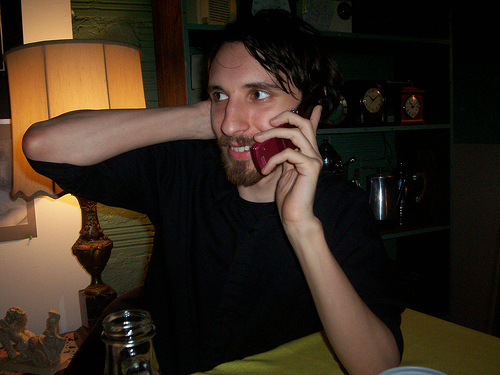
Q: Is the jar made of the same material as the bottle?
A: Yes, both the jar and the bottle are made of glass.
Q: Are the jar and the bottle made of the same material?
A: Yes, both the jar and the bottle are made of glass.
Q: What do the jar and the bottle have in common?
A: The material, both the jar and the bottle are glass.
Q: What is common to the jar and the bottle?
A: The material, both the jar and the bottle are glass.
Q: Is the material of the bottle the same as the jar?
A: Yes, both the bottle and the jar are made of glass.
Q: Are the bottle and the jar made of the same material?
A: Yes, both the bottle and the jar are made of glass.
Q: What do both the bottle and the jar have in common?
A: The material, both the bottle and the jar are glass.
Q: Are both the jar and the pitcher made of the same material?
A: No, the jar is made of glass and the pitcher is made of metal.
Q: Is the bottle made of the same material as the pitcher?
A: No, the bottle is made of glass and the pitcher is made of metal.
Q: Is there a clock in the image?
A: Yes, there is a clock.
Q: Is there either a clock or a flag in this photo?
A: Yes, there is a clock.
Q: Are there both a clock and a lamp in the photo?
A: Yes, there are both a clock and a lamp.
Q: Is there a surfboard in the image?
A: No, there are no surfboards.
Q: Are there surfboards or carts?
A: No, there are no surfboards or carts.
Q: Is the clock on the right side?
A: Yes, the clock is on the right of the image.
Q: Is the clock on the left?
A: No, the clock is on the right of the image.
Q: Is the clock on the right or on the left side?
A: The clock is on the right of the image.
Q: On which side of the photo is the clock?
A: The clock is on the right of the image.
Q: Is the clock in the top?
A: Yes, the clock is in the top of the image.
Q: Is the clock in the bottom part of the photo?
A: No, the clock is in the top of the image.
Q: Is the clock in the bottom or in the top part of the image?
A: The clock is in the top of the image.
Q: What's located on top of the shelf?
A: The clock is on top of the shelf.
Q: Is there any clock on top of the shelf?
A: Yes, there is a clock on top of the shelf.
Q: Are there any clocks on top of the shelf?
A: Yes, there is a clock on top of the shelf.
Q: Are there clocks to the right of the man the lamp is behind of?
A: Yes, there is a clock to the right of the man.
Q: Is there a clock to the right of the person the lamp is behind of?
A: Yes, there is a clock to the right of the man.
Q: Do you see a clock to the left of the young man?
A: No, the clock is to the right of the man.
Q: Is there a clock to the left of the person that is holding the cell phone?
A: No, the clock is to the right of the man.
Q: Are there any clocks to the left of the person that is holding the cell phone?
A: No, the clock is to the right of the man.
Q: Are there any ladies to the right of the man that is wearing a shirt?
A: No, there is a clock to the right of the man.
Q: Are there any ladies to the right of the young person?
A: No, there is a clock to the right of the man.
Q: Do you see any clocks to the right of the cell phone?
A: Yes, there is a clock to the right of the cell phone.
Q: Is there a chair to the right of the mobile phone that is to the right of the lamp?
A: No, there is a clock to the right of the cellphone.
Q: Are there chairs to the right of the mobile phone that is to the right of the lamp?
A: No, there is a clock to the right of the cellphone.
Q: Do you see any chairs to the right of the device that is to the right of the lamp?
A: No, there is a clock to the right of the cellphone.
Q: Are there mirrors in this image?
A: No, there are no mirrors.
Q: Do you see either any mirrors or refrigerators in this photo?
A: No, there are no mirrors or refrigerators.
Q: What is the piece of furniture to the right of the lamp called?
A: The piece of furniture is a shelf.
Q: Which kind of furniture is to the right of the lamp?
A: The piece of furniture is a shelf.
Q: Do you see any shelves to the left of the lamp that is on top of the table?
A: No, the shelf is to the right of the lamp.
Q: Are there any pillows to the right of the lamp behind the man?
A: No, there is a shelf to the right of the lamp.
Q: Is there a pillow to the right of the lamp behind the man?
A: No, there is a shelf to the right of the lamp.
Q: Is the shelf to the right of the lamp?
A: Yes, the shelf is to the right of the lamp.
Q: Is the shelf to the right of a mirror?
A: No, the shelf is to the right of the lamp.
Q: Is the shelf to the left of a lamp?
A: No, the shelf is to the right of a lamp.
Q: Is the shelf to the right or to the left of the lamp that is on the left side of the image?
A: The shelf is to the right of the lamp.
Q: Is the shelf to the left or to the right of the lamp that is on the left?
A: The shelf is to the right of the lamp.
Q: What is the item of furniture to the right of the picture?
A: The piece of furniture is a shelf.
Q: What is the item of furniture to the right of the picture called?
A: The piece of furniture is a shelf.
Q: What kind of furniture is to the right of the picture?
A: The piece of furniture is a shelf.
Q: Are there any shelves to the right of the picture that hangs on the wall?
A: Yes, there is a shelf to the right of the picture.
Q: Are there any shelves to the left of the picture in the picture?
A: No, the shelf is to the right of the picture.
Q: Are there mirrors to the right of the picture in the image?
A: No, there is a shelf to the right of the picture.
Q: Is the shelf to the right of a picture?
A: Yes, the shelf is to the right of a picture.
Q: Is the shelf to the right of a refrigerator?
A: No, the shelf is to the right of a picture.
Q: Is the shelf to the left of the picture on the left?
A: No, the shelf is to the right of the picture.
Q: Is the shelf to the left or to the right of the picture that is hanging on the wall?
A: The shelf is to the right of the picture.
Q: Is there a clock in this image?
A: Yes, there is a clock.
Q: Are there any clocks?
A: Yes, there is a clock.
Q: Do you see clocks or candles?
A: Yes, there is a clock.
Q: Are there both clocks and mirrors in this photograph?
A: No, there is a clock but no mirrors.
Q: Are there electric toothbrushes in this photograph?
A: No, there are no electric toothbrushes.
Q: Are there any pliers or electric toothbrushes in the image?
A: No, there are no electric toothbrushes or pliers.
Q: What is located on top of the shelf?
A: The clock is on top of the shelf.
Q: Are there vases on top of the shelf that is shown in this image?
A: No, there is a clock on top of the shelf.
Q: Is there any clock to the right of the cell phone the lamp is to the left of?
A: Yes, there is a clock to the right of the cell phone.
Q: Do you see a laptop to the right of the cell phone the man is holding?
A: No, there is a clock to the right of the mobile phone.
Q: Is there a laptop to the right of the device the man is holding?
A: No, there is a clock to the right of the mobile phone.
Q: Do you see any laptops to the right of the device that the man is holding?
A: No, there is a clock to the right of the mobile phone.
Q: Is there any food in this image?
A: No, there is no food.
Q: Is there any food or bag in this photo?
A: No, there are no food or bags.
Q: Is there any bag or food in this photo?
A: No, there are no food or bags.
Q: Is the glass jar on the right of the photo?
A: Yes, the jar is on the right of the image.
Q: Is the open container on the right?
A: Yes, the jar is on the right of the image.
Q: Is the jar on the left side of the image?
A: No, the jar is on the right of the image.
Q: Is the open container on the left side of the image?
A: No, the jar is on the right of the image.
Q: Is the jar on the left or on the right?
A: The jar is on the right of the image.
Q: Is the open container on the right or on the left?
A: The jar is on the right of the image.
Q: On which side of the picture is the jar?
A: The jar is on the right of the image.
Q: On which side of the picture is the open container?
A: The jar is on the right of the image.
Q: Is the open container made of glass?
A: Yes, the jar is made of glass.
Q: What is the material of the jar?
A: The jar is made of glass.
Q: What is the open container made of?
A: The jar is made of glass.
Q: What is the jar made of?
A: The jar is made of glass.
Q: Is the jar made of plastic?
A: No, the jar is made of glass.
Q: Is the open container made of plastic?
A: No, the jar is made of glass.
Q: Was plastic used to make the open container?
A: No, the jar is made of glass.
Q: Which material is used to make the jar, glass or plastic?
A: The jar is made of glass.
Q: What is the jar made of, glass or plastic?
A: The jar is made of glass.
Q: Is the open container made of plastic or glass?
A: The jar is made of glass.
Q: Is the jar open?
A: Yes, the jar is open.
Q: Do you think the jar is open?
A: Yes, the jar is open.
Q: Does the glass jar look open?
A: Yes, the jar is open.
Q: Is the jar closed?
A: No, the jar is open.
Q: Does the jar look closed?
A: No, the jar is open.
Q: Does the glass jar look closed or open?
A: The jar is open.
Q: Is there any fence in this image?
A: No, there are no fences.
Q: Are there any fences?
A: No, there are no fences.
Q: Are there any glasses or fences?
A: No, there are no fences or glasses.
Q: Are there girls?
A: No, there are no girls.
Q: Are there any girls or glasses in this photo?
A: No, there are no girls or glasses.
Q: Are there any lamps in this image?
A: Yes, there is a lamp.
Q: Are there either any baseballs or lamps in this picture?
A: Yes, there is a lamp.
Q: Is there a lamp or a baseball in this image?
A: Yes, there is a lamp.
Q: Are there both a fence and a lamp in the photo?
A: No, there is a lamp but no fences.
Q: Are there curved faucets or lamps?
A: Yes, there is a curved lamp.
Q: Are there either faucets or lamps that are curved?
A: Yes, the lamp is curved.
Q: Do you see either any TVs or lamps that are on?
A: Yes, the lamp is on.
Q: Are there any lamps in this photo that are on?
A: Yes, there is a lamp that is on.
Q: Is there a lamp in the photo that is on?
A: Yes, there is a lamp that is on.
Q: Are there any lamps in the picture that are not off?
A: Yes, there is a lamp that is on.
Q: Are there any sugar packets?
A: No, there are no sugar packets.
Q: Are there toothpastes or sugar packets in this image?
A: No, there are no sugar packets or toothpastes.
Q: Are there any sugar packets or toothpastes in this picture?
A: No, there are no sugar packets or toothpastes.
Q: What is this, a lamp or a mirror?
A: This is a lamp.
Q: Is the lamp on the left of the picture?
A: Yes, the lamp is on the left of the image.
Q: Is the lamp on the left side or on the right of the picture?
A: The lamp is on the left of the image.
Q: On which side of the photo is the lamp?
A: The lamp is on the left of the image.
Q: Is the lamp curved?
A: Yes, the lamp is curved.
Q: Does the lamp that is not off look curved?
A: Yes, the lamp is curved.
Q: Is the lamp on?
A: Yes, the lamp is on.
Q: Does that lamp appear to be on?
A: Yes, the lamp is on.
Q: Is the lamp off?
A: No, the lamp is on.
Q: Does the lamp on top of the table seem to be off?
A: No, the lamp is on.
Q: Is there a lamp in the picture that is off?
A: No, there is a lamp but it is on.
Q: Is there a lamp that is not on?
A: No, there is a lamp but it is on.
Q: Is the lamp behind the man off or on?
A: The lamp is on.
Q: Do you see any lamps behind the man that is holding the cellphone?
A: Yes, there is a lamp behind the man.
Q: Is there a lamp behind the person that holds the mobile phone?
A: Yes, there is a lamp behind the man.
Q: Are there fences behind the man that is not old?
A: No, there is a lamp behind the man.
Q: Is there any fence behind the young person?
A: No, there is a lamp behind the man.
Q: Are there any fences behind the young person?
A: No, there is a lamp behind the man.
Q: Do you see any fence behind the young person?
A: No, there is a lamp behind the man.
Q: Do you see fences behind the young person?
A: No, there is a lamp behind the man.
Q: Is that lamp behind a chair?
A: No, the lamp is behind the man.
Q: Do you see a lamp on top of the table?
A: Yes, there is a lamp on top of the table.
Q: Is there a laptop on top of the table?
A: No, there is a lamp on top of the table.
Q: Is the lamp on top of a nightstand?
A: No, the lamp is on top of a table.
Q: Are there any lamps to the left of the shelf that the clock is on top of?
A: Yes, there is a lamp to the left of the shelf.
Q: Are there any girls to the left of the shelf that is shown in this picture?
A: No, there is a lamp to the left of the shelf.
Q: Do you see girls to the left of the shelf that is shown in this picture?
A: No, there is a lamp to the left of the shelf.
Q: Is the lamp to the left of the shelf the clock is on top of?
A: Yes, the lamp is to the left of the shelf.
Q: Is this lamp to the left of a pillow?
A: No, the lamp is to the left of the shelf.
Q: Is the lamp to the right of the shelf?
A: No, the lamp is to the left of the shelf.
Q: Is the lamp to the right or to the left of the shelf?
A: The lamp is to the left of the shelf.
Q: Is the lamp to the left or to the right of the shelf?
A: The lamp is to the left of the shelf.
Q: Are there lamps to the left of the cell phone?
A: Yes, there is a lamp to the left of the cell phone.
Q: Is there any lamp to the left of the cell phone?
A: Yes, there is a lamp to the left of the cell phone.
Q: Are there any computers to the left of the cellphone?
A: No, there is a lamp to the left of the cellphone.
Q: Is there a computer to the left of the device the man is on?
A: No, there is a lamp to the left of the cellphone.